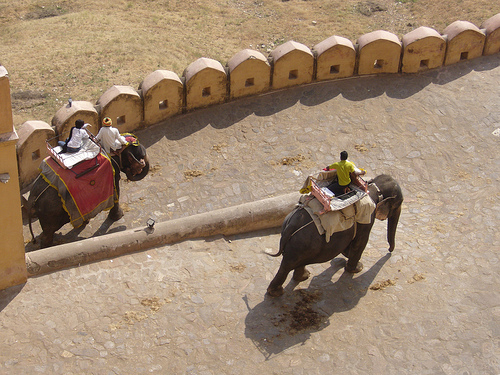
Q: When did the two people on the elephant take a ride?
A: Mid afternoon.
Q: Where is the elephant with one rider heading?
A: To the right.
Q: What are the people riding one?
A: Elephants.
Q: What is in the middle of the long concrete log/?
A: A metal loop.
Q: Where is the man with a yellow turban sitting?
A: On the elephants head.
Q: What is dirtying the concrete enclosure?
A: Poop.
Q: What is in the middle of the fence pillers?
A: Holes.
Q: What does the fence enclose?
A: The elephant arena.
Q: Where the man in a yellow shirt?
A: On the leading elephant.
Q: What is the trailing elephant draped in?
A: Red cloth.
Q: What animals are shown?
A: Elephants.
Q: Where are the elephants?
A: On the ground.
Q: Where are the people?
A: On the elephants.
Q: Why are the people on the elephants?
A: To ride.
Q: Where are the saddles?
A: On the elephants.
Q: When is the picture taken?
A: Daytime.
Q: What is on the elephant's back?
A: People.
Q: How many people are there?
A: 3.